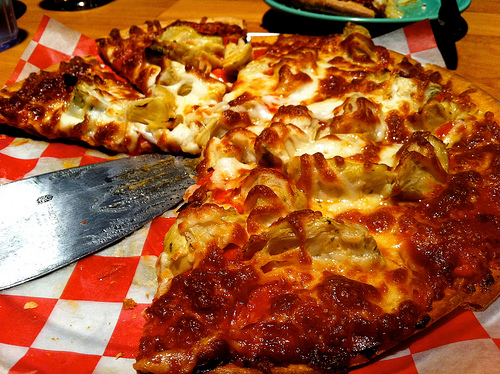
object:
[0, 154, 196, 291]
utensil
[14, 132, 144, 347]
paper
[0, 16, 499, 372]
pizza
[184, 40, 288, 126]
cheese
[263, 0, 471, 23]
plate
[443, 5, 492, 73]
table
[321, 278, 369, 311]
peppers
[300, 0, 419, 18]
food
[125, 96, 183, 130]
chicken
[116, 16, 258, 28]
crust